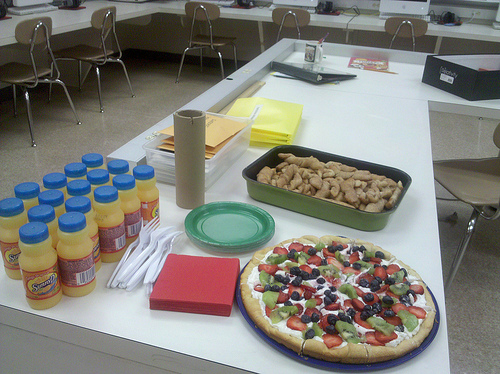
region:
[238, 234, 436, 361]
Fruit pizza slices topped with kiwi, strawberries and blueberries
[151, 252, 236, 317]
Red paper napkins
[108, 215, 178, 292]
Bunch of white plastic forks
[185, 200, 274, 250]
Stack of green waxed paper plates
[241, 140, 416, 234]
Green roasting dish filled with chicken tenders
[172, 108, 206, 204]
Roll of brown paper towels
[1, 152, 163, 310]
Bottles of SunnyD orange juice on a table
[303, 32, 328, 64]
white mug holding pens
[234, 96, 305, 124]
labeled yellow folder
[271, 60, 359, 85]
black ring folder on the table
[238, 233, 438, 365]
a large fruit pizza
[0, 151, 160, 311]
small bottles of Sunny D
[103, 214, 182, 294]
pile of white plastic forks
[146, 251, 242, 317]
pile of red napkins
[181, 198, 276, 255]
pile of small green plates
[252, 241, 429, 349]
strawberries kiwi and blueberries toppings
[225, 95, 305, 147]
yellow binder on table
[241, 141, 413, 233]
tray of chicken on table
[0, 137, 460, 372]
white table with food and drinks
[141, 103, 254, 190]
plastic bucket of envelopes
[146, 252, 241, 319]
Pile of red napkins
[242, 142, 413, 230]
Long green pan with black interior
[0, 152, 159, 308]
Several small bottles of Sunny D with blue caps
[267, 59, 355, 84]
Black ring binder on white table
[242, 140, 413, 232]
Pan of breaded chicken tenders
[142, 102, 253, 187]
Plastic bin with envelopes in it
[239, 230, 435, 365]
A pizza topped with blueberries and strawberry and kiwi slices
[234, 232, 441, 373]
Fruit pizza on a blue plate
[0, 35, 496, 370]
White l-shaped desk some food an office items on it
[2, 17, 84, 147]
Metal framed chair with beige seat and backrest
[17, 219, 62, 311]
bottle of sunny D on table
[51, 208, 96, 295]
bottle of sunny D on table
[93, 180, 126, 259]
bottle of sunny d on table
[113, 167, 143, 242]
bottle of sunny d on table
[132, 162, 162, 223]
bottle of sunny d on table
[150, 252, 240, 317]
red napkins on table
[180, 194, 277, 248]
green paper plates on table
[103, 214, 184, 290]
plastic fork laying on table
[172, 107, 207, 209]
cardboard tube standing up on table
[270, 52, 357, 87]
paper binder on table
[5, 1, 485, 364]
food on long counter in neat classroom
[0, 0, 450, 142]
gray chairs under white desks with computers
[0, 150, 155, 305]
plastic bottles of juice with blue caps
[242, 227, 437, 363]
dessert pizza with berries in creamy topping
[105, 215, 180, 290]
plastic white forks with tines turned away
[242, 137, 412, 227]
green oblong pan with brown chicken strips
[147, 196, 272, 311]
red napkins next to green plates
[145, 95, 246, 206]
tube by plastic bin of envelopes and folders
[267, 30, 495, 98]
binder, mug, card and box at end of table